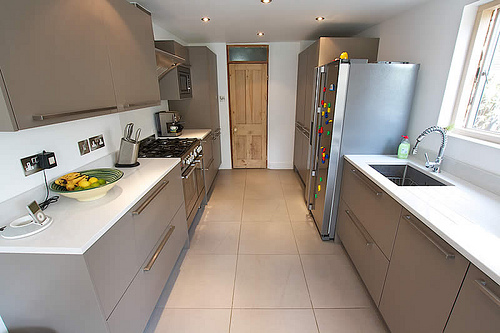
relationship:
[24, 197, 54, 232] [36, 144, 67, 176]
player on charger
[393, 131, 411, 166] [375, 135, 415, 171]
detergent next to sink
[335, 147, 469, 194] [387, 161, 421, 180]
sink with soap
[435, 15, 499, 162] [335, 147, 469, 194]
window behind sink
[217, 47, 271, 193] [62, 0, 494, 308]
door in room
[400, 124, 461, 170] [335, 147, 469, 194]
faucet on sink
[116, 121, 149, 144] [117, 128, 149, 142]
knives on top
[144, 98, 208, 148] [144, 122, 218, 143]
maker on countertop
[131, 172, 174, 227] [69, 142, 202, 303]
handle on drawer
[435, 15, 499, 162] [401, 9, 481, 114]
window on wall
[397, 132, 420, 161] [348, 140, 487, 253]
bottle on countertop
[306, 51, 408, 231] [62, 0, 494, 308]
refrigerator in kitchen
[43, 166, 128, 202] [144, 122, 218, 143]
bowl on countertop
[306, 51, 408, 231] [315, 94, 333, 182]
refrigerator with magnets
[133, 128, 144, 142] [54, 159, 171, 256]
knife on counter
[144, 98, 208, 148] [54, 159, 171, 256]
maker on counter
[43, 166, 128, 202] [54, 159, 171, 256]
bowl on counter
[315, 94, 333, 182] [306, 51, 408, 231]
magnets on refrigerator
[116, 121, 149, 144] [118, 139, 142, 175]
knives in holder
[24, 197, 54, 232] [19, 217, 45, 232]
player in stand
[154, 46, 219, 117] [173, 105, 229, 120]
microwave above range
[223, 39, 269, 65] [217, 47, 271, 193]
transom over door